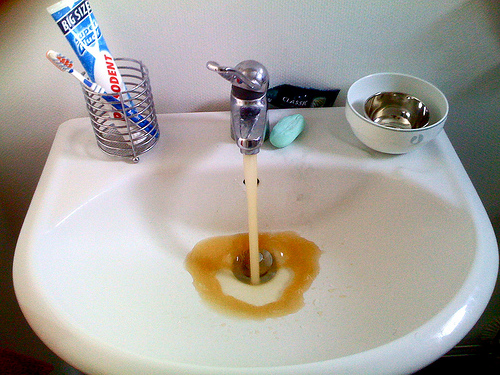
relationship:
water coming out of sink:
[233, 147, 267, 292] [8, 94, 498, 373]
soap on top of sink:
[267, 112, 305, 147] [8, 94, 498, 373]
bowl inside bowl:
[362, 89, 432, 131] [342, 68, 454, 158]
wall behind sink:
[3, 1, 494, 373] [8, 94, 498, 373]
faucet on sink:
[202, 41, 271, 153] [8, 94, 498, 373]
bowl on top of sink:
[342, 68, 454, 158] [8, 94, 498, 373]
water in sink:
[184, 155, 326, 317] [8, 94, 498, 373]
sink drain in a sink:
[233, 247, 276, 283] [8, 94, 498, 373]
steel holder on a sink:
[73, 52, 165, 167] [8, 94, 498, 373]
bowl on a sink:
[342, 68, 454, 158] [8, 94, 498, 373]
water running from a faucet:
[184, 155, 326, 317] [203, 52, 273, 153]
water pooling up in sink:
[183, 221, 332, 309] [50, 57, 473, 352]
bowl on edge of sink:
[342, 68, 454, 158] [8, 94, 498, 373]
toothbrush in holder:
[47, 51, 132, 105] [78, 62, 172, 153]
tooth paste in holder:
[43, 5, 153, 140] [77, 52, 161, 160]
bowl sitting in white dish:
[362, 89, 432, 131] [346, 69, 449, 163]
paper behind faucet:
[267, 85, 339, 110] [203, 58, 270, 155]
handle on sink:
[193, 48, 269, 138] [8, 94, 498, 373]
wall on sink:
[413, 142, 473, 189] [8, 94, 498, 373]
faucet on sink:
[206, 60, 271, 156] [8, 94, 498, 373]